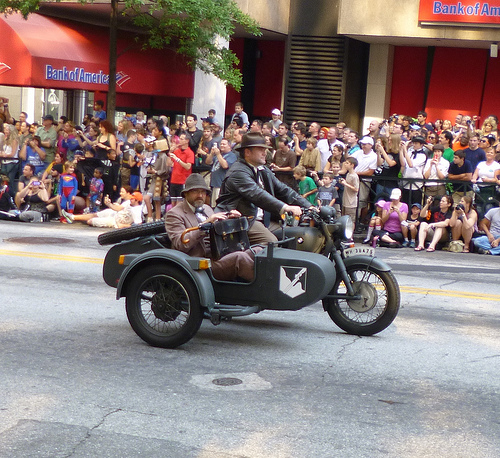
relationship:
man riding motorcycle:
[220, 125, 319, 237] [90, 196, 407, 358]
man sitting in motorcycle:
[163, 169, 272, 279] [97, 193, 400, 350]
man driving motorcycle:
[220, 125, 319, 237] [90, 196, 407, 358]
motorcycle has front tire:
[90, 196, 407, 358] [319, 254, 402, 339]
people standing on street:
[3, 98, 216, 186] [3, 201, 91, 239]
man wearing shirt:
[220, 125, 319, 237] [247, 166, 272, 190]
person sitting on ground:
[377, 187, 411, 245] [361, 242, 478, 270]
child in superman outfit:
[50, 157, 84, 215] [51, 172, 85, 214]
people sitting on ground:
[365, 179, 499, 253] [361, 242, 478, 270]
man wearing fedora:
[220, 125, 319, 237] [233, 128, 281, 151]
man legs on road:
[55, 186, 131, 225] [3, 201, 91, 239]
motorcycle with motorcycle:
[90, 196, 407, 358] [97, 193, 400, 350]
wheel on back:
[94, 215, 170, 249] [89, 203, 168, 284]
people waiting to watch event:
[3, 98, 216, 186] [7, 129, 499, 446]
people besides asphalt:
[3, 98, 216, 186] [0, 350, 500, 451]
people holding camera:
[28, 116, 58, 146] [31, 117, 45, 128]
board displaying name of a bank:
[409, 2, 499, 35] [432, 1, 499, 21]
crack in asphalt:
[76, 391, 132, 448] [0, 325, 500, 452]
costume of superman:
[85, 177, 104, 210] [89, 180, 104, 204]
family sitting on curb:
[365, 179, 499, 253] [380, 252, 499, 278]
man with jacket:
[220, 125, 319, 237] [211, 160, 314, 228]